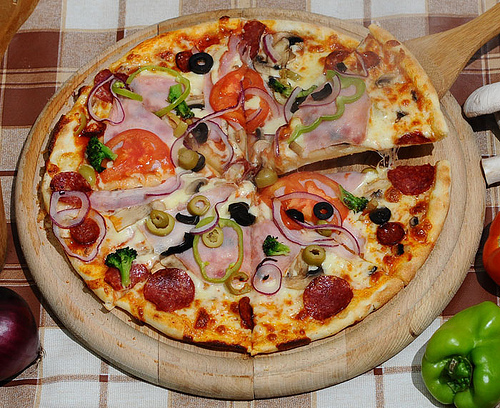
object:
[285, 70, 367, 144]
vegetables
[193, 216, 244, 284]
vegetables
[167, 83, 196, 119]
vegetables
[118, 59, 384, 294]
cheese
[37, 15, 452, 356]
pizza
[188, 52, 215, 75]
olive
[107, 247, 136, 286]
broccoli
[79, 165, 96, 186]
green olives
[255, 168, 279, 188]
green olives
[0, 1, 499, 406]
table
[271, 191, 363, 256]
red onion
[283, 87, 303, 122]
red onion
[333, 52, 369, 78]
red onion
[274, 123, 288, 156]
red onion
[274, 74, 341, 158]
red onion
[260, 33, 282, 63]
red onion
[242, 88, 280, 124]
red onion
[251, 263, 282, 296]
red onion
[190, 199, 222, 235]
red onion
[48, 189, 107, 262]
red onion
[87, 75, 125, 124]
red onion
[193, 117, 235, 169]
red onion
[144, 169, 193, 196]
red onion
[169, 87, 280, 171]
red onion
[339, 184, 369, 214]
broccoli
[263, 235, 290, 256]
broccoli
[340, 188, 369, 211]
broccoli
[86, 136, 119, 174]
broccoli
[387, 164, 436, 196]
pepperoni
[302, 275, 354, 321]
pepperoni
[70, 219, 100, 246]
pepperoni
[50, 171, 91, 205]
pepperoni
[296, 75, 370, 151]
ham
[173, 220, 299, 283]
ham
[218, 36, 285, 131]
ham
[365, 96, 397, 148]
cheese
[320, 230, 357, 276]
cheese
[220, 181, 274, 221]
cheese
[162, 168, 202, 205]
cheese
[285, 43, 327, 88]
cheese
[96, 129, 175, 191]
tomato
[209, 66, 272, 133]
tomato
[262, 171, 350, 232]
tomato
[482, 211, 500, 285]
tomato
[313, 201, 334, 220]
olive slice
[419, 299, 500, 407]
bell pepper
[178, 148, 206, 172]
mushrooms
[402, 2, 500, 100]
handle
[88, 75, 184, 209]
ham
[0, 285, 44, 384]
onion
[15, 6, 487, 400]
board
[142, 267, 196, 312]
pepperoni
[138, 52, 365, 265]
topping